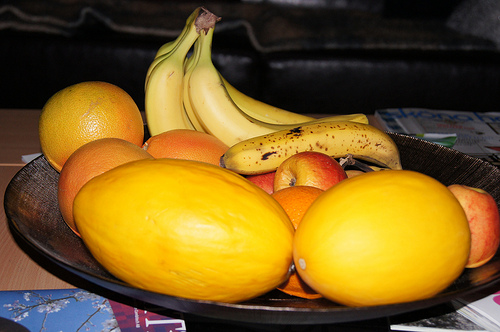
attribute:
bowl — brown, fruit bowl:
[8, 168, 58, 275]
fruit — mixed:
[124, 18, 386, 260]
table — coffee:
[1, 98, 499, 327]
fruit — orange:
[22, 63, 160, 163]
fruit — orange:
[292, 153, 479, 303]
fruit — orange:
[65, 160, 310, 285]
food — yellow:
[85, 159, 300, 299]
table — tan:
[1, 55, 53, 164]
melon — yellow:
[279, 159, 473, 321]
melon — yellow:
[66, 162, 297, 293]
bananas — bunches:
[108, 8, 367, 196]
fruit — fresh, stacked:
[37, 5, 497, 305]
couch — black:
[232, 12, 498, 98]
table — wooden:
[0, 107, 385, 291]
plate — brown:
[1, 124, 481, 330]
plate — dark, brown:
[5, 102, 499, 330]